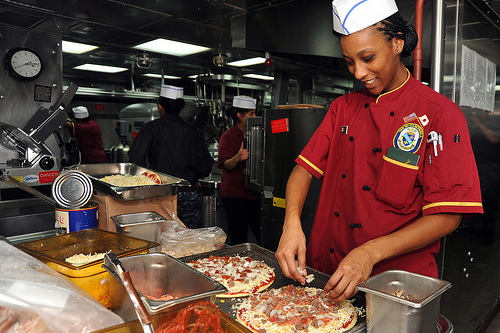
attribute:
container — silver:
[355, 266, 453, 331]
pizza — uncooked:
[235, 283, 357, 332]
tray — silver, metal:
[175, 239, 366, 332]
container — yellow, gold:
[16, 227, 161, 308]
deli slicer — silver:
[1, 83, 82, 192]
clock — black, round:
[4, 45, 44, 81]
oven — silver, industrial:
[242, 107, 442, 252]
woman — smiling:
[273, 0, 483, 305]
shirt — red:
[293, 67, 486, 286]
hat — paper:
[332, 0, 399, 38]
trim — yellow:
[421, 200, 484, 212]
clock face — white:
[11, 50, 41, 78]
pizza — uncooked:
[185, 254, 275, 299]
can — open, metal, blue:
[51, 169, 100, 236]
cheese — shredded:
[65, 249, 113, 265]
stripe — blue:
[333, 0, 371, 35]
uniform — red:
[216, 125, 263, 199]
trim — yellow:
[297, 152, 324, 177]